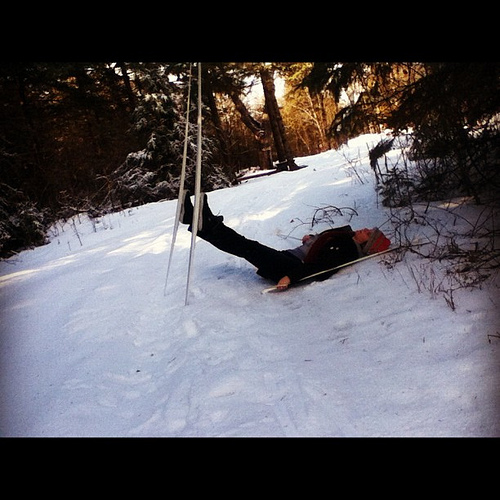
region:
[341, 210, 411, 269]
the head of a woman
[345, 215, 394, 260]
the face of a woman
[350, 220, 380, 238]
the nose of a woman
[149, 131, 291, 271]
the feet of a woman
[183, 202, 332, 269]
the legs of a woman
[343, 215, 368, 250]
the chin of a woman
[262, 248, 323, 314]
the hand of a woman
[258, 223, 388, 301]
the arm of a woman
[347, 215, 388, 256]
the eye of a woman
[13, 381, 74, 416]
White snow covering the ground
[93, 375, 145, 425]
White snow covering the ground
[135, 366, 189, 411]
White snow covering the ground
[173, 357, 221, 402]
White snow covering the ground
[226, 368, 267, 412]
White snow covering the ground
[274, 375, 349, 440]
White snow covering the ground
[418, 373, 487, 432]
White snow covering the ground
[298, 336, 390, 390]
White snow covering the ground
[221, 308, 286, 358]
White snow covering the ground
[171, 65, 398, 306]
skier laying on ground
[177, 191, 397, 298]
skier laying on snow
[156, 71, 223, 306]
long skis on skier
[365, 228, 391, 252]
red hat of skier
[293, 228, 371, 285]
black jacket of skier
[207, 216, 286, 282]
black pants of skier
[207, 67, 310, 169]
tree standing in forest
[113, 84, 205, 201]
snow covered branches of tree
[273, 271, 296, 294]
hand of woman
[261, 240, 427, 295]
ski pole on ground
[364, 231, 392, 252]
Person wearing hat on head.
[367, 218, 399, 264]
Person's hat is red and gray.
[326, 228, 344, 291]
Person wearing dark coat.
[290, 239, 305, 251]
Person wearing gray shirt.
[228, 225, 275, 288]
Person wearing black pants.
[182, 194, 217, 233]
Person wearing black and white boots.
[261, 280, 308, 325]
Person holding ski pole in hand.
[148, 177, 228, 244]
2 skis on person's feet.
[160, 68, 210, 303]
two pairs of white skis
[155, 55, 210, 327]
white skis in the air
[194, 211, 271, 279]
black pants on person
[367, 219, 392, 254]
red beanie on head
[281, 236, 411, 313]
white ski pole on ground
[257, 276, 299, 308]
hand holding white ski pole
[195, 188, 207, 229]
black ski shoes on feet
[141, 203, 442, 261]
person laying in the snow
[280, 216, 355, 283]
black ski jacket on person